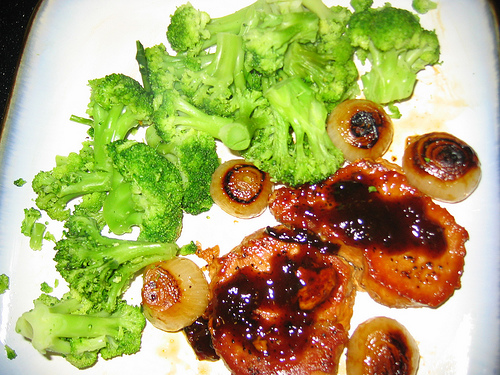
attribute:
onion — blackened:
[265, 89, 499, 306]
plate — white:
[0, 1, 500, 373]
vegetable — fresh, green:
[259, 78, 334, 174]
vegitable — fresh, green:
[38, 59, 203, 332]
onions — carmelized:
[173, 86, 479, 216]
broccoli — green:
[37, 16, 267, 233]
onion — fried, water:
[322, 80, 409, 173]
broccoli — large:
[178, 34, 321, 143]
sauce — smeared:
[155, 335, 215, 373]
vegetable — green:
[74, 260, 147, 375]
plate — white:
[55, 340, 145, 375]